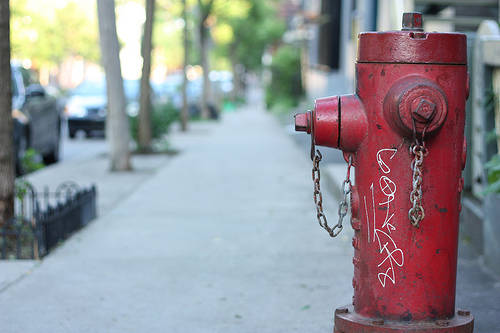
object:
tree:
[171, 0, 196, 131]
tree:
[195, 0, 214, 118]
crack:
[1, 252, 48, 292]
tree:
[128, 0, 168, 156]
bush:
[262, 41, 305, 110]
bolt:
[408, 95, 439, 124]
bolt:
[456, 307, 469, 317]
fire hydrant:
[293, 9, 475, 332]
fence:
[28, 177, 99, 258]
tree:
[92, 0, 132, 172]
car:
[11, 61, 66, 177]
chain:
[309, 139, 356, 238]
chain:
[404, 114, 431, 228]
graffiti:
[361, 144, 407, 289]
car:
[63, 74, 161, 140]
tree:
[223, 0, 286, 108]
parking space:
[13, 130, 121, 180]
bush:
[128, 100, 181, 154]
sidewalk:
[0, 101, 360, 331]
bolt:
[367, 315, 387, 328]